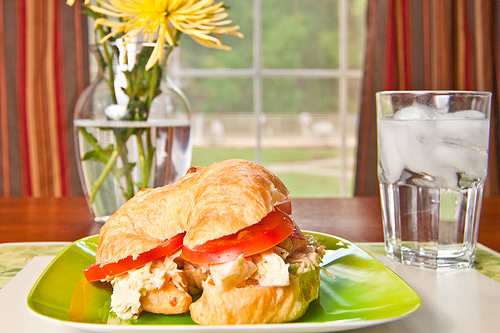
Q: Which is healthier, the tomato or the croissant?
A: The tomato is healthier than the croissant.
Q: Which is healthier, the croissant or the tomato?
A: The tomato is healthier than the croissant.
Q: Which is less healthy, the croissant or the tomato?
A: The croissant is less healthy than the tomato.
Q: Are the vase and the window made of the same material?
A: Yes, both the vase and the window are made of glass.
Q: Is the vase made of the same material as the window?
A: Yes, both the vase and the window are made of glass.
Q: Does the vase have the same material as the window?
A: Yes, both the vase and the window are made of glass.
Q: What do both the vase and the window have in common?
A: The material, both the vase and the window are glass.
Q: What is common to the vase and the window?
A: The material, both the vase and the window are glass.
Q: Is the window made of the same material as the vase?
A: Yes, both the window and the vase are made of glass.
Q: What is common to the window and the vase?
A: The material, both the window and the vase are glass.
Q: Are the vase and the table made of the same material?
A: No, the vase is made of glass and the table is made of wood.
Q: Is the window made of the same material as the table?
A: No, the window is made of glass and the table is made of wood.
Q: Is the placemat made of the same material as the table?
A: No, the placemat is made of plastic and the table is made of wood.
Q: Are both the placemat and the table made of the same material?
A: No, the placemat is made of plastic and the table is made of wood.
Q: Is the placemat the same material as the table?
A: No, the placemat is made of plastic and the table is made of wood.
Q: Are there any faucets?
A: No, there are no faucets.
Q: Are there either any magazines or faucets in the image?
A: No, there are no faucets or magazines.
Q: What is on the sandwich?
A: The chicken is on the sandwich.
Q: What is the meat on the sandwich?
A: The meat is chicken.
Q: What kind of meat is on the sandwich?
A: The meat is chicken.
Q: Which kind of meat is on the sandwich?
A: The meat is chicken.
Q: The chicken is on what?
A: The chicken is on the sandwich.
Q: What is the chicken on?
A: The chicken is on the sandwich.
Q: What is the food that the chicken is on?
A: The food is a sandwich.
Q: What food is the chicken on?
A: The chicken is on the sandwich.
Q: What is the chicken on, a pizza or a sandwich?
A: The chicken is on a sandwich.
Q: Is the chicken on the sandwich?
A: Yes, the chicken is on the sandwich.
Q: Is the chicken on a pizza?
A: No, the chicken is on the sandwich.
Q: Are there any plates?
A: Yes, there is a plate.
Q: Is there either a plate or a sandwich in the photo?
A: Yes, there is a plate.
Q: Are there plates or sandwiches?
A: Yes, there is a plate.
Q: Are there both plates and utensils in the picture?
A: No, there is a plate but no utensils.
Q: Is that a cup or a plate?
A: That is a plate.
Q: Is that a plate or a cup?
A: That is a plate.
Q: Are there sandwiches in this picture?
A: Yes, there is a sandwich.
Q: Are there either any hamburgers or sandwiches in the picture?
A: Yes, there is a sandwich.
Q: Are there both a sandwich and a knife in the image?
A: No, there is a sandwich but no knives.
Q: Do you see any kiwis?
A: No, there are no kiwis.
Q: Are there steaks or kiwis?
A: No, there are no kiwis or steaks.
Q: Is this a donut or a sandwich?
A: This is a sandwich.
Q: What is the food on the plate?
A: The food is a sandwich.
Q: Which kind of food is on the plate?
A: The food is a sandwich.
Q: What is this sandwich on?
A: The sandwich is on the plate.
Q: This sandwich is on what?
A: The sandwich is on the plate.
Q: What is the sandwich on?
A: The sandwich is on the plate.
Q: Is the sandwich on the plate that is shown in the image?
A: Yes, the sandwich is on the plate.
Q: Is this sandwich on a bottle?
A: No, the sandwich is on the plate.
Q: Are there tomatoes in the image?
A: Yes, there is a tomato.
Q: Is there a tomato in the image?
A: Yes, there is a tomato.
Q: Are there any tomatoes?
A: Yes, there is a tomato.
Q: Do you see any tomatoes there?
A: Yes, there is a tomato.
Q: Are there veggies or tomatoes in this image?
A: Yes, there is a tomato.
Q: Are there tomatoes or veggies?
A: Yes, there is a tomato.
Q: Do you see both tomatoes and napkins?
A: No, there is a tomato but no napkins.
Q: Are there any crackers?
A: No, there are no crackers.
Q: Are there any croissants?
A: Yes, there is a croissant.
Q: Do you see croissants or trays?
A: Yes, there is a croissant.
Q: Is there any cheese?
A: No, there is no cheese.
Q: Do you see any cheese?
A: No, there is no cheese.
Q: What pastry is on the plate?
A: The pastry is a croissant.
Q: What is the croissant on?
A: The croissant is on the plate.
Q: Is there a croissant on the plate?
A: Yes, there is a croissant on the plate.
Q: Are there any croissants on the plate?
A: Yes, there is a croissant on the plate.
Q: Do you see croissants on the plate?
A: Yes, there is a croissant on the plate.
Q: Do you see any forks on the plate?
A: No, there is a croissant on the plate.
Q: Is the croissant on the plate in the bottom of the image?
A: Yes, the croissant is on the plate.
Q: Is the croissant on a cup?
A: No, the croissant is on the plate.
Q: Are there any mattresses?
A: No, there are no mattresses.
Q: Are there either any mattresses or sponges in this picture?
A: No, there are no mattresses or sponges.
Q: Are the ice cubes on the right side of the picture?
A: Yes, the ice cubes are on the right of the image.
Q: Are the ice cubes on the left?
A: No, the ice cubes are on the right of the image.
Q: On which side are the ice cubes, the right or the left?
A: The ice cubes are on the right of the image.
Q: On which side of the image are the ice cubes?
A: The ice cubes are on the right of the image.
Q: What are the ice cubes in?
A: The ice cubes are in the glass.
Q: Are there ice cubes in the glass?
A: Yes, there are ice cubes in the glass.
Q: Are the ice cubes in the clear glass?
A: Yes, the ice cubes are in the glass.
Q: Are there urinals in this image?
A: No, there are no urinals.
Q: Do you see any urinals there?
A: No, there are no urinals.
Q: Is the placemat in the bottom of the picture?
A: Yes, the placemat is in the bottom of the image.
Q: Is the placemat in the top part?
A: No, the placemat is in the bottom of the image.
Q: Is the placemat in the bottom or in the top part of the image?
A: The placemat is in the bottom of the image.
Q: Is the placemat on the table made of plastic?
A: Yes, the placemat is made of plastic.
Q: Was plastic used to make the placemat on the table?
A: Yes, the placemat is made of plastic.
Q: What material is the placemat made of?
A: The placemat is made of plastic.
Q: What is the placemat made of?
A: The placemat is made of plastic.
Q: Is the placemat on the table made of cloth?
A: No, the placemat is made of plastic.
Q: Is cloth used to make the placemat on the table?
A: No, the placemat is made of plastic.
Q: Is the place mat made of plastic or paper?
A: The place mat is made of plastic.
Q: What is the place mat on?
A: The place mat is on the table.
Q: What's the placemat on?
A: The place mat is on the table.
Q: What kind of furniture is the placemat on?
A: The placemat is on the table.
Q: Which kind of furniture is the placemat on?
A: The placemat is on the table.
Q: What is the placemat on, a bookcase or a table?
A: The placemat is on a table.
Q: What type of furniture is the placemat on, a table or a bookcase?
A: The placemat is on a table.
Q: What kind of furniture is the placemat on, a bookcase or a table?
A: The placemat is on a table.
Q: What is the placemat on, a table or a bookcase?
A: The placemat is on a table.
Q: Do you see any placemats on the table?
A: Yes, there is a placemat on the table.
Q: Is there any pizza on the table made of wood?
A: No, there is a placemat on the table.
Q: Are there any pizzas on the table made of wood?
A: No, there is a placemat on the table.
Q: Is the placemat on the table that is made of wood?
A: Yes, the placemat is on the table.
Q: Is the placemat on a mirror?
A: No, the placemat is on the table.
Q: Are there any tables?
A: Yes, there is a table.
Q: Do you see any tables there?
A: Yes, there is a table.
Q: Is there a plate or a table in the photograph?
A: Yes, there is a table.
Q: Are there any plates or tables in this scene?
A: Yes, there is a table.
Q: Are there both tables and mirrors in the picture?
A: No, there is a table but no mirrors.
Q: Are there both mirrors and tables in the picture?
A: No, there is a table but no mirrors.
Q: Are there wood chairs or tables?
A: Yes, there is a wood table.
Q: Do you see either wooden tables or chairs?
A: Yes, there is a wood table.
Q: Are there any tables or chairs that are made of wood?
A: Yes, the table is made of wood.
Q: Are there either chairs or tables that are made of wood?
A: Yes, the table is made of wood.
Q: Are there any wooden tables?
A: Yes, there is a wood table.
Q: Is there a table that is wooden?
A: Yes, there is a table that is wooden.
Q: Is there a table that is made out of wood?
A: Yes, there is a table that is made of wood.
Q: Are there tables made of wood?
A: Yes, there is a table that is made of wood.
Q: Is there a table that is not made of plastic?
A: Yes, there is a table that is made of wood.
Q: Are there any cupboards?
A: No, there are no cupboards.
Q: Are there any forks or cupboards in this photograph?
A: No, there are no cupboards or forks.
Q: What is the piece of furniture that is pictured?
A: The piece of furniture is a table.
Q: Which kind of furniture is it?
A: The piece of furniture is a table.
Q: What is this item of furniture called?
A: This is a table.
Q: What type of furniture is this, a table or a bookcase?
A: This is a table.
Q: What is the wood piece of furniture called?
A: The piece of furniture is a table.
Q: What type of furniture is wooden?
A: The furniture is a table.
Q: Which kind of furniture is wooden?
A: The furniture is a table.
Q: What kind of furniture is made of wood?
A: The furniture is a table.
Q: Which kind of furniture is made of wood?
A: The furniture is a table.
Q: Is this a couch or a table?
A: This is a table.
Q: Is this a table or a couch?
A: This is a table.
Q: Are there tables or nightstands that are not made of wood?
A: No, there is a table but it is made of wood.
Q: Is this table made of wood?
A: Yes, the table is made of wood.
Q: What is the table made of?
A: The table is made of wood.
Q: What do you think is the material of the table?
A: The table is made of wood.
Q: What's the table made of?
A: The table is made of wood.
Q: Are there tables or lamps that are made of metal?
A: No, there is a table but it is made of wood.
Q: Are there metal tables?
A: No, there is a table but it is made of wood.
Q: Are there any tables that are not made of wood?
A: No, there is a table but it is made of wood.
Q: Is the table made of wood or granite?
A: The table is made of wood.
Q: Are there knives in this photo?
A: No, there are no knives.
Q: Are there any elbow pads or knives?
A: No, there are no knives or elbow pads.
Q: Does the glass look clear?
A: Yes, the glass is clear.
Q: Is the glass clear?
A: Yes, the glass is clear.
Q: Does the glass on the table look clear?
A: Yes, the glass is clear.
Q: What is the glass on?
A: The glass is on the table.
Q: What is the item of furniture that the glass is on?
A: The piece of furniture is a table.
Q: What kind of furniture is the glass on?
A: The glass is on the table.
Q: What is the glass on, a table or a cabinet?
A: The glass is on a table.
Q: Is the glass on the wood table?
A: Yes, the glass is on the table.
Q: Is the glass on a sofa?
A: No, the glass is on the table.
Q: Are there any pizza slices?
A: No, there are no pizza slices.